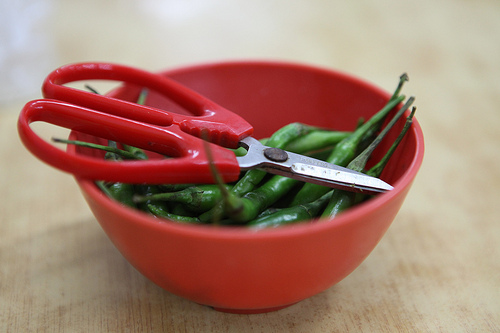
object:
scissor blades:
[240, 130, 404, 196]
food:
[214, 190, 341, 220]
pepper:
[51, 133, 146, 165]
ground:
[472, 163, 477, 175]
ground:
[400, 123, 425, 157]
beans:
[256, 70, 418, 175]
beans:
[90, 165, 380, 229]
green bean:
[331, 72, 411, 162]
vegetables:
[50, 70, 420, 232]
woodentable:
[434, 52, 472, 139]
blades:
[241, 136, 394, 193]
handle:
[16, 99, 240, 184]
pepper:
[128, 183, 232, 210]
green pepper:
[104, 65, 414, 222]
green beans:
[51, 72, 416, 229]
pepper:
[146, 201, 197, 223]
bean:
[395, 72, 411, 81]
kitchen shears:
[17, 59, 397, 194]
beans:
[52, 73, 415, 228]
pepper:
[192, 123, 382, 238]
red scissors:
[23, 56, 396, 196]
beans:
[253, 82, 404, 228]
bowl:
[63, 57, 425, 314]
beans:
[93, 103, 400, 221]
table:
[0, 2, 496, 332]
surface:
[446, 210, 496, 324]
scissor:
[119, 97, 391, 195]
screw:
[264, 147, 289, 162]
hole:
[28, 115, 185, 164]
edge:
[361, 71, 416, 169]